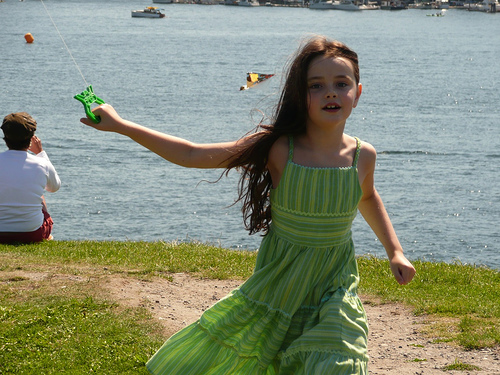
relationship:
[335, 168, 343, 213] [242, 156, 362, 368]
yellow stripe on dress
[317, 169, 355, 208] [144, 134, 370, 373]
stripe on dress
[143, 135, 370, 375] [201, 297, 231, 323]
dress has edge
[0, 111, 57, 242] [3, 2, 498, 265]
person near water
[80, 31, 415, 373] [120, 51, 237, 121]
girl near water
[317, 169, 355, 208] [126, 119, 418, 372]
stripe on dress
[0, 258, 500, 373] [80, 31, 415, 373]
dirt near girl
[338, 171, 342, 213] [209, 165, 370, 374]
yellow stripe on dress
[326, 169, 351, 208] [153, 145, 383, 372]
stripe on dress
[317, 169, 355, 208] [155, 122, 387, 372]
stripe on dress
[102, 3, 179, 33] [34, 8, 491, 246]
boat on water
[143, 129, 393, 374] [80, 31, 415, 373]
dress on girl